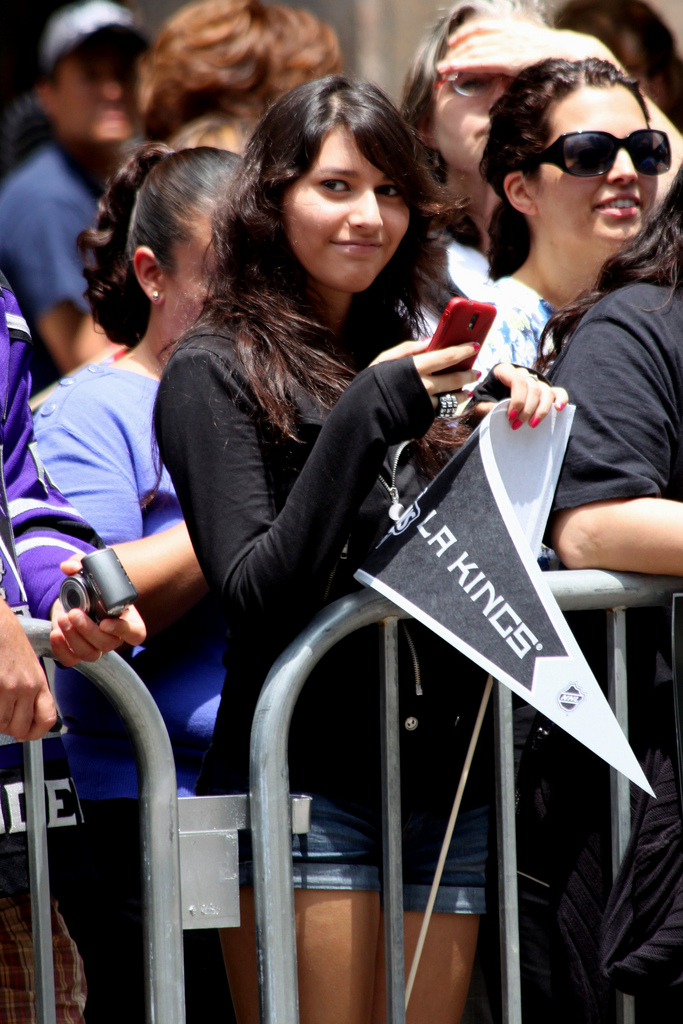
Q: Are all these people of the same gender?
A: No, they are both male and female.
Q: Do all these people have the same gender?
A: No, they are both male and female.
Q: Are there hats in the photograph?
A: Yes, there is a hat.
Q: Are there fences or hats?
A: Yes, there is a hat.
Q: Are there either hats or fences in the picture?
A: Yes, there is a hat.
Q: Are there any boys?
A: No, there are no boys.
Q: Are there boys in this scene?
A: No, there are no boys.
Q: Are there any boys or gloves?
A: No, there are no boys or gloves.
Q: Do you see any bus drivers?
A: No, there are no bus drivers.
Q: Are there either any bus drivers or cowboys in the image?
A: No, there are no bus drivers or cowboys.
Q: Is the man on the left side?
A: Yes, the man is on the left of the image.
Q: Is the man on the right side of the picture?
A: No, the man is on the left of the image.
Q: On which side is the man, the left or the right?
A: The man is on the left of the image.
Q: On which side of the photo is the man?
A: The man is on the left of the image.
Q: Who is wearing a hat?
A: The man is wearing a hat.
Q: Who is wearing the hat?
A: The man is wearing a hat.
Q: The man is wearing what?
A: The man is wearing a hat.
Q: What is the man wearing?
A: The man is wearing a hat.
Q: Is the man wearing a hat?
A: Yes, the man is wearing a hat.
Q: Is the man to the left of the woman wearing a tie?
A: No, the man is wearing a hat.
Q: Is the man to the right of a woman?
A: No, the man is to the left of a woman.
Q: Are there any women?
A: Yes, there is a woman.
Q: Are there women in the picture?
A: Yes, there is a woman.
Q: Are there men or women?
A: Yes, there is a woman.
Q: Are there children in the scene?
A: No, there are no children.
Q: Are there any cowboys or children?
A: No, there are no children or cowboys.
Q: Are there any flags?
A: Yes, there is a flag.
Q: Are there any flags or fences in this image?
A: Yes, there is a flag.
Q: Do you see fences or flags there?
A: Yes, there is a flag.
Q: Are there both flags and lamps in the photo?
A: No, there is a flag but no lamps.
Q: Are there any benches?
A: No, there are no benches.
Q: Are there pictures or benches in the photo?
A: No, there are no benches or pictures.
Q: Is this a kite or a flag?
A: This is a flag.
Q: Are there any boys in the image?
A: No, there are no boys.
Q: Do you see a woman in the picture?
A: Yes, there is a woman.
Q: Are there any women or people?
A: Yes, there is a woman.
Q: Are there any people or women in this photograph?
A: Yes, there is a woman.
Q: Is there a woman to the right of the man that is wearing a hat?
A: Yes, there is a woman to the right of the man.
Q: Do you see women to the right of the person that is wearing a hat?
A: Yes, there is a woman to the right of the man.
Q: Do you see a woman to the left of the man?
A: No, the woman is to the right of the man.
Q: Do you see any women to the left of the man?
A: No, the woman is to the right of the man.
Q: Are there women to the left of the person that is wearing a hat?
A: No, the woman is to the right of the man.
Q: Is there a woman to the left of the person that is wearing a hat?
A: No, the woman is to the right of the man.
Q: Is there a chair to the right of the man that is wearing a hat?
A: No, there is a woman to the right of the man.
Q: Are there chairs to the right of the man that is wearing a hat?
A: No, there is a woman to the right of the man.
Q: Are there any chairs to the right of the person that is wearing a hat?
A: No, there is a woman to the right of the man.